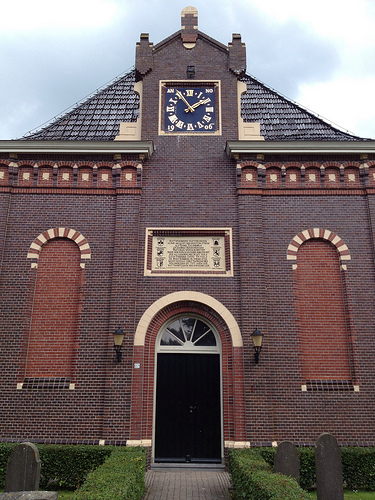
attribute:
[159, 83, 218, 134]
clock — square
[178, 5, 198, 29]
logo — cross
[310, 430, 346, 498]
tombstone — gray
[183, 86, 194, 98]
12 — number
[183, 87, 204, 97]
numerals — roman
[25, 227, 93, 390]
window — bricked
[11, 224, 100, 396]
wall — red, brick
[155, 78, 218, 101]
numeral — roman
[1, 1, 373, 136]
sky — blue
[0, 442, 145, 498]
bushes — shaved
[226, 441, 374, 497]
bushes — shaved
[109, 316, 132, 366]
light — small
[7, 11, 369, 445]
church — red, brick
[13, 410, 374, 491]
bushes — trimmed, green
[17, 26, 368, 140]
shingled roof — gray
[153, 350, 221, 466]
double doors — black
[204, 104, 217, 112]
numeral — roman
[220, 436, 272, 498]
bushes — green, trimmed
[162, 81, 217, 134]
clock — 1:50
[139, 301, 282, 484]
door — black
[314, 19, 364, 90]
clouds — white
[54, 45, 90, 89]
sky — blue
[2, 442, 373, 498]
hedges — green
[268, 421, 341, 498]
tombstones — gray, old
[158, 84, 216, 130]
clock — blue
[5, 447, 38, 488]
tombstone — gray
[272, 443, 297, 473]
tombstone — gray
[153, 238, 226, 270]
plaque — large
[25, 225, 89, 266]
top — rounded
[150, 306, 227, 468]
doorway — arched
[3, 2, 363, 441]
wall — brick, red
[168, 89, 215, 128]
face — blue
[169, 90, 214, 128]
numbers — roman numerals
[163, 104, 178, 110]
number — roman numeral, 9